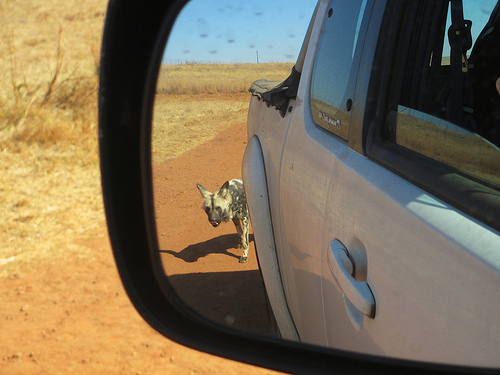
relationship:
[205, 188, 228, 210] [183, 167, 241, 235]
line on head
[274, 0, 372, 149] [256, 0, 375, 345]
window on door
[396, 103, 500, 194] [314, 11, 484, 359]
window on door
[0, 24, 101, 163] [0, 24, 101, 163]
plant and plant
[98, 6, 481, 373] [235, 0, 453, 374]
mirror on car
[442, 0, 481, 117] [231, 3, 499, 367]
seatbelt in car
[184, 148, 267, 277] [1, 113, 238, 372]
hyena on side of road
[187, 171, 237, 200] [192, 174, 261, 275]
ears of hyena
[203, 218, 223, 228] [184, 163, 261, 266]
nose of hyena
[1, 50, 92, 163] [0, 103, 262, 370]
plant on side of road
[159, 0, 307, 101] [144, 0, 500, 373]
water mark on mirror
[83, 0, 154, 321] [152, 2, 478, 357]
trim of mirror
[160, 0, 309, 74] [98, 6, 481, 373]
sky in mirror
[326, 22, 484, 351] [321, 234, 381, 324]
door with handle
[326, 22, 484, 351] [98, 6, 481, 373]
door seen in mirror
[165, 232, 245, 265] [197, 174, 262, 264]
shadow of dog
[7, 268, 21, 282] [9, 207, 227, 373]
rock by road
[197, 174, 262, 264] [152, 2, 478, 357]
dog reflecting in mirror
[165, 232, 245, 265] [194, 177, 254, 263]
shadow of dog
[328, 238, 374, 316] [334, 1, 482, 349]
handle on door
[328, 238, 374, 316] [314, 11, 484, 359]
handle on door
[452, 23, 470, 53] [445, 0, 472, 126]
buckle of a seatbelt